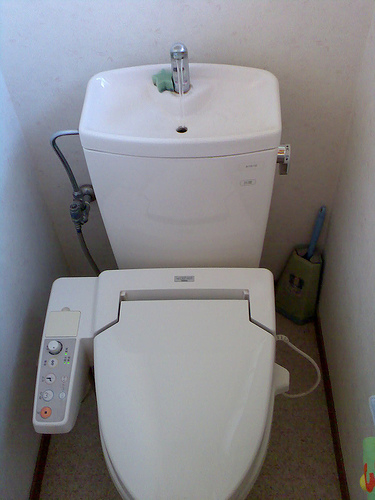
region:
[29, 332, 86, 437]
Panel with round buttons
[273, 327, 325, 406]
Thin white curved cable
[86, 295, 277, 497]
Toilet seat cover lowered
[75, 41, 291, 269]
Long white shiny cistern with sink top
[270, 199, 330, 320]
Container with a toilet brush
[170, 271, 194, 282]
Branding patch on a white surface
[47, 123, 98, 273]
Think curved silver piping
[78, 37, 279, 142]
Flowing tap over a sink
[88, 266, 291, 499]
Toilet seat beneath coverer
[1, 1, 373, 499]
Toilet wall with white walls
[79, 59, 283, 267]
white ceramic toilet tank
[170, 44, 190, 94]
silver can on toilet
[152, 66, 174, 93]
green candle on toilet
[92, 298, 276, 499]
white plastic toilet lid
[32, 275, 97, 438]
white control panel on toilet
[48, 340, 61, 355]
white dial on toilet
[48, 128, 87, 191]
silver pipe on toilet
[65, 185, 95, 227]
metal valve on pipe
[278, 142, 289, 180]
silver handle on toilet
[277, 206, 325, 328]
toilet scrubber on floor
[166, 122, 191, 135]
small hole on top of toilet top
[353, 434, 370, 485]
green paint on side of wall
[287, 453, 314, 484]
tan tiles on the floor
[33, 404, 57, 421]
small pink circle on toilet lever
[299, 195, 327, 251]
blue top on toilet bowl cleaner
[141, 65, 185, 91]
small blue stopper on top of toilet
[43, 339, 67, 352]
small white button on the side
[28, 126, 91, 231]
silver pipe attached to the toilet seat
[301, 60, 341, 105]
white paint on the wall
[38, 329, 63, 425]
buttons on the right side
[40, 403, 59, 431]
orange button on the bottom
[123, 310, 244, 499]
lid of toilet is down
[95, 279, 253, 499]
a white toilet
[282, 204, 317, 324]
cleaning brush and bowl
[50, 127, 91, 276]
plumbing fixtures in the back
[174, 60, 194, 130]
water coming out of faucet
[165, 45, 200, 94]
chrome faucet on top of toilet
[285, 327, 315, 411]
coil on side of toilet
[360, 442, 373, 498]
orange green item on wall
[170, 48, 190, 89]
The faucet on top of the toilet.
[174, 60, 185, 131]
The water coming out of the faucet.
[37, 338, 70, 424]
The button panel on the armrest of the toilet..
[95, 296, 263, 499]
The lid of the toilet.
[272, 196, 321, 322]
The toilet bowl brush.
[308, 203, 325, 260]
The handle of the toilet bowl brush.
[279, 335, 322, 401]
The white wire on the side of the toilet.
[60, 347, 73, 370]
The green lights on the button panel.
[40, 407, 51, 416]
The orange button on the button panel.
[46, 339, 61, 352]
The white knob on the button panel.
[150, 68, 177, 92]
Green star soap next to the faucet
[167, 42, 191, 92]
Faucet above the sink is on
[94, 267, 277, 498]
Toilet seat is white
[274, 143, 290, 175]
Silver flush handle on the toilet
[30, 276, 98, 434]
Electronic pad on the toilet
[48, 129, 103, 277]
Plumbing pipe next to the toilet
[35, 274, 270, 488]
a toilet in the bathroom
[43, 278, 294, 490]
a bathroom toilet is white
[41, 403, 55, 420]
a button on the toilet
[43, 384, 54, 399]
a button on the toilet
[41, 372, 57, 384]
a button on the toilet